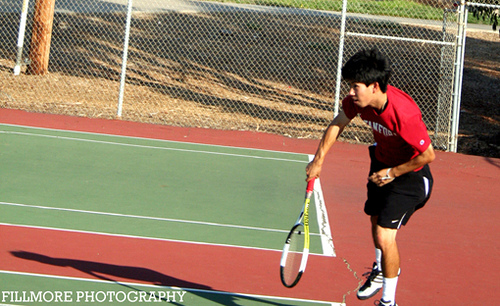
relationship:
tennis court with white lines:
[3, 121, 347, 304] [0, 194, 342, 251]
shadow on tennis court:
[14, 243, 273, 304] [0, 107, 496, 304]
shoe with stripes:
[349, 260, 390, 300] [374, 272, 382, 285]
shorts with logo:
[363, 147, 436, 227] [386, 215, 402, 228]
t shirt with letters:
[342, 86, 432, 170] [361, 115, 393, 141]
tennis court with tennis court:
[0, 103, 500, 306] [0, 103, 500, 306]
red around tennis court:
[7, 121, 480, 288] [0, 107, 496, 304]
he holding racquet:
[306, 48, 438, 304] [281, 168, 319, 291]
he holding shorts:
[302, 48, 439, 306] [363, 145, 437, 231]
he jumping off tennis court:
[302, 48, 439, 306] [0, 103, 500, 306]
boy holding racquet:
[308, 45, 433, 303] [275, 179, 333, 288]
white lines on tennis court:
[27, 132, 342, 303] [0, 103, 500, 306]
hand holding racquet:
[303, 156, 325, 186] [279, 171, 319, 288]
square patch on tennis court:
[0, 122, 338, 257] [0, 107, 496, 304]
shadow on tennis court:
[5, 248, 299, 306] [0, 107, 496, 304]